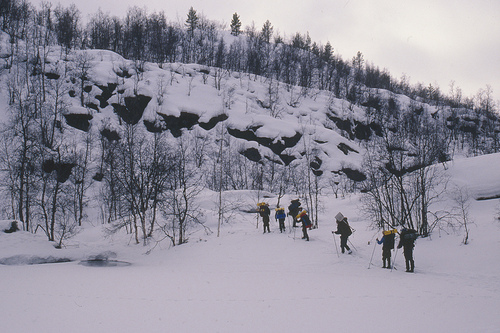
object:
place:
[1, 0, 497, 333]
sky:
[99, 0, 500, 108]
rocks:
[69, 84, 304, 154]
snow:
[0, 45, 500, 333]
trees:
[92, 9, 119, 46]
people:
[256, 202, 270, 234]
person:
[330, 212, 352, 255]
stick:
[330, 230, 339, 258]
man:
[396, 228, 420, 272]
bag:
[405, 232, 419, 241]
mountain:
[0, 4, 500, 177]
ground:
[3, 156, 500, 333]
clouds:
[264, 4, 496, 70]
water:
[77, 257, 131, 267]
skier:
[376, 229, 398, 269]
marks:
[416, 269, 488, 285]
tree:
[183, 4, 200, 36]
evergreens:
[5, 1, 489, 110]